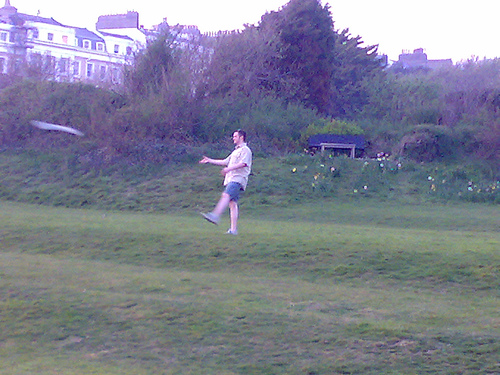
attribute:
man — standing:
[198, 130, 251, 235]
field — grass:
[1, 197, 499, 371]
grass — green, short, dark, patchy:
[4, 72, 498, 373]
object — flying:
[32, 121, 81, 138]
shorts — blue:
[225, 183, 242, 203]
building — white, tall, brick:
[1, 1, 218, 90]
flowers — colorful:
[290, 147, 497, 193]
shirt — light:
[222, 142, 252, 188]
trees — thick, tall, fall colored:
[137, 1, 387, 122]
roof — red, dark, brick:
[0, 5, 206, 47]